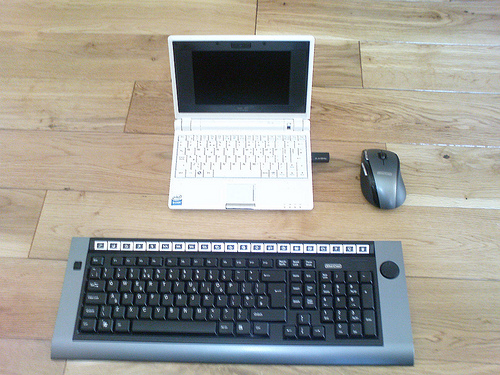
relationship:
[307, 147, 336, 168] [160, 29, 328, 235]
usb inserted to laptop